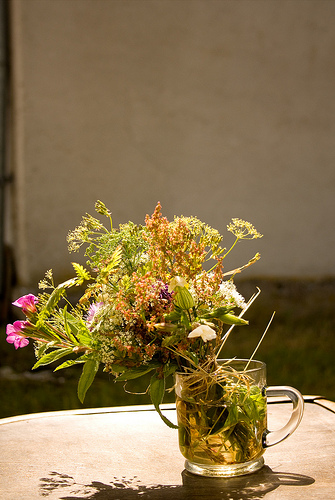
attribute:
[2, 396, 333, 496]
surface — dirty, brown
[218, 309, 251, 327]
leaf — green, small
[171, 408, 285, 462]
water — brown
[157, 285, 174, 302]
flower — purple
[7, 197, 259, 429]
flowers — multi color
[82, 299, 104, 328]
purple flower — small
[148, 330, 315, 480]
mug — glassy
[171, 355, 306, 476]
cup — clear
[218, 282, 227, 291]
flower — white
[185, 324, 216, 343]
flower — white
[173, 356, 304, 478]
vase — clear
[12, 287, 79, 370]
purple flower — small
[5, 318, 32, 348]
purple flower — small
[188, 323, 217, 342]
flower — small, white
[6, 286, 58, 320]
flower — purple, small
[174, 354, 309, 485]
mug — glassy